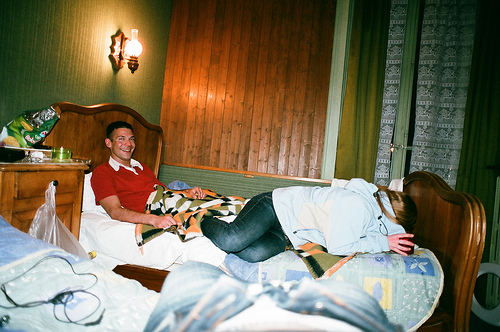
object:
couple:
[90, 121, 416, 264]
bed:
[41, 102, 486, 331]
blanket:
[143, 248, 445, 331]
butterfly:
[409, 259, 428, 272]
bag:
[1, 106, 62, 149]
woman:
[200, 184, 416, 263]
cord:
[0, 254, 107, 327]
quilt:
[135, 183, 247, 249]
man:
[89, 121, 205, 231]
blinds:
[159, 0, 338, 179]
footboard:
[402, 170, 487, 332]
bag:
[27, 181, 91, 259]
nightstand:
[0, 162, 89, 242]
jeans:
[197, 191, 294, 263]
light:
[119, 27, 145, 73]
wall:
[0, 0, 174, 130]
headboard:
[46, 102, 163, 177]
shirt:
[90, 156, 167, 213]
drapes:
[373, 0, 476, 189]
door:
[389, 0, 500, 180]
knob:
[50, 180, 61, 186]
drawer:
[13, 172, 78, 198]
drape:
[334, 0, 393, 182]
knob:
[388, 142, 409, 152]